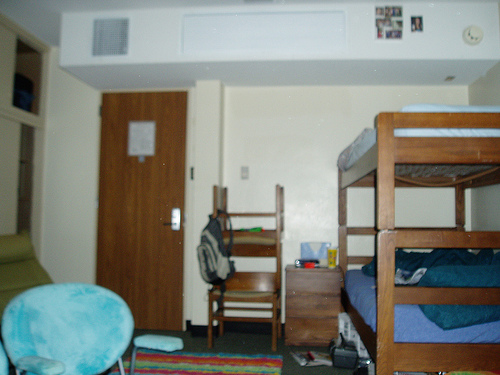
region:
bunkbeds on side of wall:
[325, 95, 490, 362]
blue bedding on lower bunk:
[341, 245, 486, 345]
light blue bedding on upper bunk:
[336, 96, 493, 146]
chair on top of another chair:
[195, 165, 295, 350]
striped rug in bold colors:
[121, 340, 281, 370]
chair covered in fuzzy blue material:
[5, 267, 142, 367]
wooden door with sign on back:
[87, 75, 192, 340]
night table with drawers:
[275, 240, 345, 360]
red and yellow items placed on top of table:
[285, 235, 340, 270]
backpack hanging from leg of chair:
[177, 171, 244, 291]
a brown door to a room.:
[94, 73, 185, 328]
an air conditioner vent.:
[73, 13, 148, 63]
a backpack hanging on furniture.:
[197, 197, 246, 304]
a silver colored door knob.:
[162, 206, 188, 237]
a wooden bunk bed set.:
[337, 100, 497, 355]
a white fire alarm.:
[453, 19, 489, 57]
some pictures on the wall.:
[352, 2, 429, 49]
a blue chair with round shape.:
[0, 285, 135, 365]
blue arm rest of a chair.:
[121, 330, 201, 358]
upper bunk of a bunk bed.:
[327, 86, 498, 230]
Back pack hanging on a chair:
[196, 202, 235, 289]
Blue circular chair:
[2, 280, 142, 372]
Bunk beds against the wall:
[324, 99, 499, 372]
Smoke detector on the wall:
[460, 20, 487, 52]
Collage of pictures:
[360, 0, 428, 55]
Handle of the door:
[160, 207, 185, 239]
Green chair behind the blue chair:
[0, 231, 54, 326]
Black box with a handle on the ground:
[324, 331, 360, 373]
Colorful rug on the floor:
[95, 348, 290, 373]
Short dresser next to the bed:
[279, 259, 344, 349]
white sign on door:
[118, 115, 173, 159]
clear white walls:
[253, 103, 336, 141]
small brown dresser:
[276, 263, 351, 353]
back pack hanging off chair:
[184, 206, 242, 306]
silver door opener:
[141, 198, 185, 236]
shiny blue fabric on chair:
[4, 277, 144, 364]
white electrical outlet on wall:
[233, 153, 257, 200]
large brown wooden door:
[85, 75, 212, 318]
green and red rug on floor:
[135, 340, 281, 374]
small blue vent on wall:
[75, 5, 158, 69]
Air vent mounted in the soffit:
[87, 15, 136, 57]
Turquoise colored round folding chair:
[1, 265, 135, 374]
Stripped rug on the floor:
[136, 345, 286, 373]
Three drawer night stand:
[286, 232, 348, 350]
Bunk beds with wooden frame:
[332, 103, 497, 368]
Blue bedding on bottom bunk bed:
[347, 258, 489, 337]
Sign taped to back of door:
[120, 105, 169, 193]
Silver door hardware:
[153, 199, 190, 249]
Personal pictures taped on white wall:
[362, 3, 439, 57]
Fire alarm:
[459, 14, 492, 56]